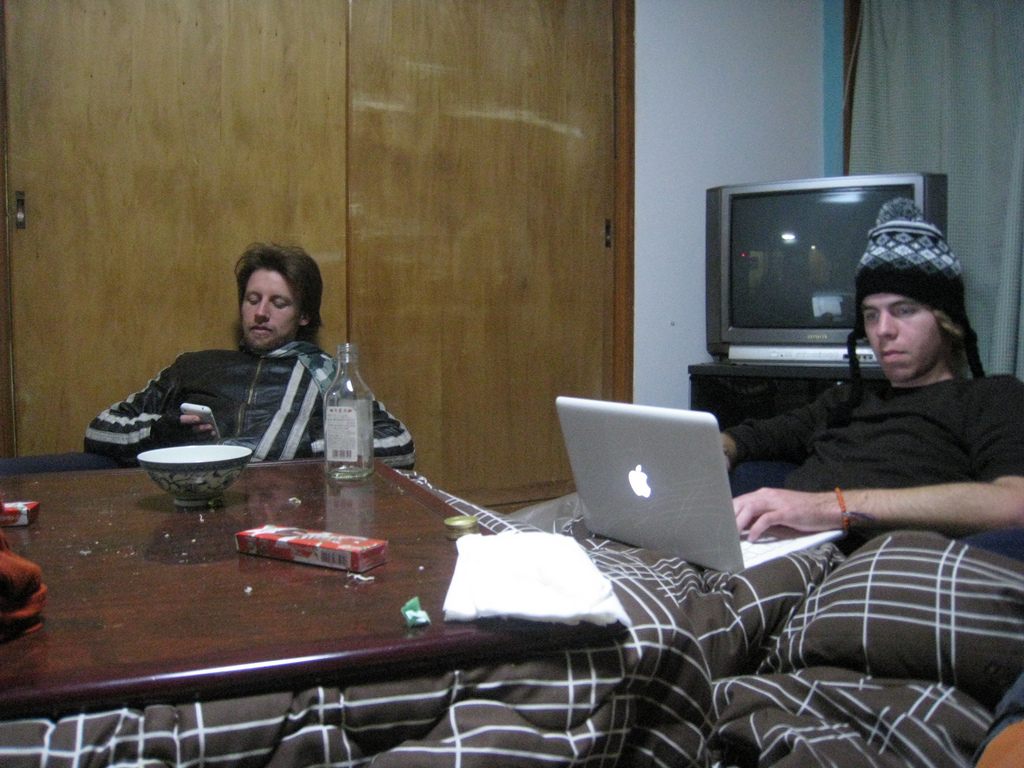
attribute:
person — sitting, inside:
[706, 264, 974, 463]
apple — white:
[623, 459, 661, 506]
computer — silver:
[541, 384, 844, 573]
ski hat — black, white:
[835, 193, 992, 419]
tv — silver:
[692, 161, 955, 378]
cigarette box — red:
[234, 515, 390, 579]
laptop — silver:
[547, 382, 841, 580]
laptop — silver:
[505, 382, 787, 609]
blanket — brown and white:
[276, 565, 977, 768]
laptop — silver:
[531, 365, 799, 614]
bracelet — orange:
[823, 476, 876, 548]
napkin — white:
[449, 513, 666, 676]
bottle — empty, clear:
[304, 329, 376, 492]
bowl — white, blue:
[125, 424, 260, 520]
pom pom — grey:
[860, 180, 943, 247]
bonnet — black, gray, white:
[823, 186, 977, 303]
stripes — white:
[244, 359, 314, 446]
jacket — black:
[86, 346, 398, 470]